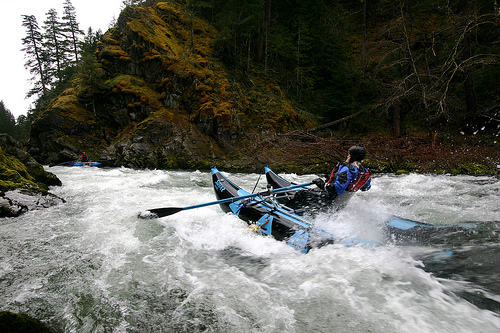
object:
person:
[308, 139, 373, 217]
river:
[63, 172, 486, 324]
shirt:
[338, 166, 361, 187]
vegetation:
[428, 157, 486, 173]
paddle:
[138, 202, 186, 224]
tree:
[15, 0, 90, 104]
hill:
[47, 89, 113, 127]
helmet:
[350, 149, 364, 157]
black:
[171, 207, 175, 212]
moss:
[166, 156, 178, 161]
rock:
[120, 121, 176, 168]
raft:
[221, 184, 315, 239]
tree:
[1, 99, 21, 132]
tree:
[288, 25, 310, 93]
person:
[77, 150, 93, 163]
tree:
[239, 10, 266, 83]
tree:
[329, 15, 358, 77]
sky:
[0, 13, 117, 121]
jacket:
[340, 162, 368, 192]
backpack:
[358, 173, 367, 191]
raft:
[74, 164, 97, 167]